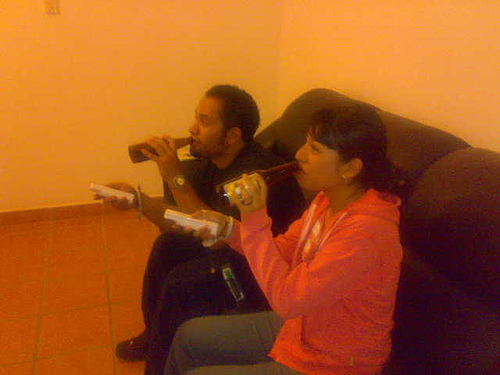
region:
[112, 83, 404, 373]
two people sitting on a couch drinking beer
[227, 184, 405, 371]
pink hoodie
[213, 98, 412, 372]
woman drinking a beer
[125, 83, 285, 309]
man drinking a beer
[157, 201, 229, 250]
hand holding a video game controller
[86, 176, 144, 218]
hand holding a video game controller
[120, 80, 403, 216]
two people drinking beer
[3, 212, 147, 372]
tile floor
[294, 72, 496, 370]
brown couch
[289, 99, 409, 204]
woman with her hair in a pony tail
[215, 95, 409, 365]
woman wearing a pink sweater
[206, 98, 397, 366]
woman wearing jean pants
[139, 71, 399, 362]
couple sitting on the sofa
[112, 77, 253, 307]
man wearing black shirt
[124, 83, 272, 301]
man wearing black pants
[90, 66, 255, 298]
man holding a WII controller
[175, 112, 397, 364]
woman playing the WII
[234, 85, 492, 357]
big plush brown sofa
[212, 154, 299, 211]
brown beer bottle in a woman's hand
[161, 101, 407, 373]
woman holding a beer bottle and wii remote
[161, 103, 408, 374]
woman drinking and playing Wii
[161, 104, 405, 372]
woman sitting on a couch while drinking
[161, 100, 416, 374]
woman with a beer bottle to her mouth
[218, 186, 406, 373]
pink hooded sweater on a woman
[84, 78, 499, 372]
man and woman sitting on a couch while drinking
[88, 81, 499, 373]
man and woman drinking and playing Wii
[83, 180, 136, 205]
wii remote in a man's hand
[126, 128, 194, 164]
beer bottle in a man's hand and mouth